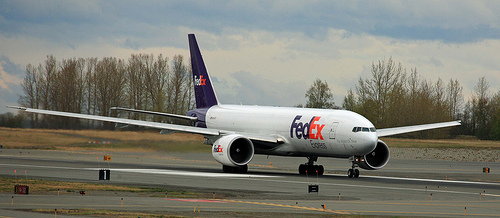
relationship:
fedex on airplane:
[286, 112, 331, 143] [103, 30, 473, 200]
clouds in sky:
[260, 27, 317, 63] [118, 15, 393, 79]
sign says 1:
[97, 169, 117, 185] [100, 169, 109, 180]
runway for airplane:
[30, 145, 472, 207] [103, 30, 473, 200]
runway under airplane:
[30, 145, 472, 207] [103, 30, 473, 200]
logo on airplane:
[286, 112, 331, 143] [103, 30, 473, 200]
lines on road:
[133, 160, 281, 187] [30, 145, 472, 207]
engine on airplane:
[211, 128, 271, 175] [103, 30, 473, 200]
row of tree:
[76, 70, 137, 111] [28, 53, 91, 91]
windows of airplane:
[350, 122, 378, 136] [103, 30, 473, 200]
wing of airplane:
[26, 90, 222, 146] [103, 30, 473, 200]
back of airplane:
[160, 58, 240, 129] [103, 30, 473, 200]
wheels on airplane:
[296, 158, 327, 179] [103, 30, 473, 200]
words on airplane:
[284, 115, 348, 172] [103, 30, 473, 200]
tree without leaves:
[28, 53, 91, 91] [139, 70, 159, 91]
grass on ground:
[28, 129, 87, 151] [67, 126, 221, 203]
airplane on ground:
[103, 30, 473, 200] [67, 126, 221, 203]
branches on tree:
[76, 70, 137, 111] [28, 53, 91, 91]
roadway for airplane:
[30, 145, 472, 207] [103, 30, 473, 200]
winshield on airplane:
[350, 122, 374, 131] [103, 30, 473, 200]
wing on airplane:
[26, 90, 222, 146] [103, 30, 473, 200]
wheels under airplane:
[296, 158, 327, 179] [103, 30, 473, 200]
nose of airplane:
[331, 116, 384, 159] [103, 30, 473, 200]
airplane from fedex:
[103, 30, 473, 200] [286, 112, 331, 143]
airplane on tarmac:
[103, 30, 473, 200] [30, 145, 472, 207]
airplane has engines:
[103, 30, 473, 200] [209, 137, 393, 180]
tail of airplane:
[182, 37, 223, 119] [103, 30, 473, 200]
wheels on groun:
[296, 158, 327, 179] [141, 124, 327, 177]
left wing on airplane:
[367, 108, 464, 151] [20, 28, 468, 184]